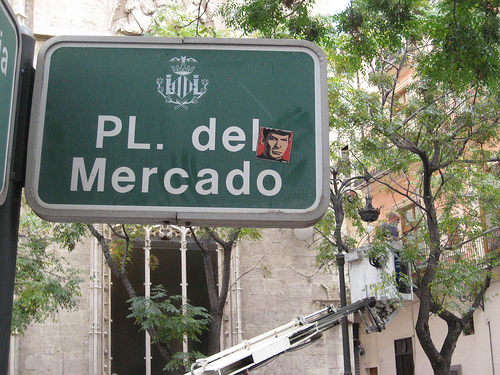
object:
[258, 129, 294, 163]
star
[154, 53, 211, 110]
crest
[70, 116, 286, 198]
letters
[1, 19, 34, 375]
black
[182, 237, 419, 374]
extended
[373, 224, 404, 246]
shirt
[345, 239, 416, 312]
basket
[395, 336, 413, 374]
metal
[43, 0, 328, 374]
trees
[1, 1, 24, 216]
edge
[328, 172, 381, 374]
black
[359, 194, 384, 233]
lamp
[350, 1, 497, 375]
trees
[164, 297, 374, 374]
white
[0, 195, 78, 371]
tree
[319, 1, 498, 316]
leaves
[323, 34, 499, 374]
side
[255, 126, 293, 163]
image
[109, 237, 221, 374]
dark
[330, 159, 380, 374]
pole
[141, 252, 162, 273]
shape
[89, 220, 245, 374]
frame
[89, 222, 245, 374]
stone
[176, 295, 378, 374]
arm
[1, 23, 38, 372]
pole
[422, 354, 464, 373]
trunk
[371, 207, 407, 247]
man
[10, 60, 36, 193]
bracket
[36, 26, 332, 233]
sign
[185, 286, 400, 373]
construction boom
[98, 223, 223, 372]
doorway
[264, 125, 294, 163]
sticker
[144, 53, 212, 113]
symbol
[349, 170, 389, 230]
bulb holder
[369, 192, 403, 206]
brick